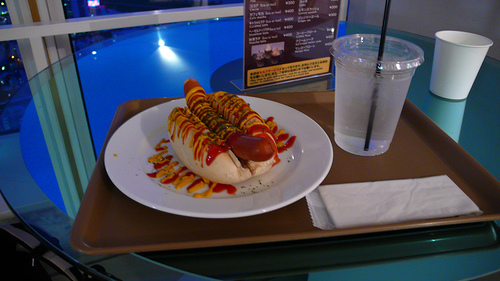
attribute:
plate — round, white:
[102, 94, 334, 219]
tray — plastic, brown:
[67, 86, 499, 256]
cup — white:
[427, 27, 494, 103]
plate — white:
[95, 37, 326, 228]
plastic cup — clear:
[325, 29, 423, 154]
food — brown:
[162, 84, 291, 189]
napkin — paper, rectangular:
[302, 173, 482, 224]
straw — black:
[360, 0, 400, 156]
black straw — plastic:
[375, 0, 395, 58]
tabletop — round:
[68, 87, 487, 262]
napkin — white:
[303, 172, 485, 229]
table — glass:
[101, 62, 496, 250]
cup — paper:
[430, 23, 497, 104]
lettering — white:
[244, 2, 342, 92]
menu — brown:
[242, 1, 334, 81]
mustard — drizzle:
[189, 85, 234, 143]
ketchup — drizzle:
[199, 137, 231, 166]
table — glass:
[8, 12, 484, 275]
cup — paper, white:
[425, 26, 485, 103]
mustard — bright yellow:
[186, 90, 256, 136]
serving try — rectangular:
[72, 92, 499, 250]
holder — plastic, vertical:
[234, 1, 346, 95]